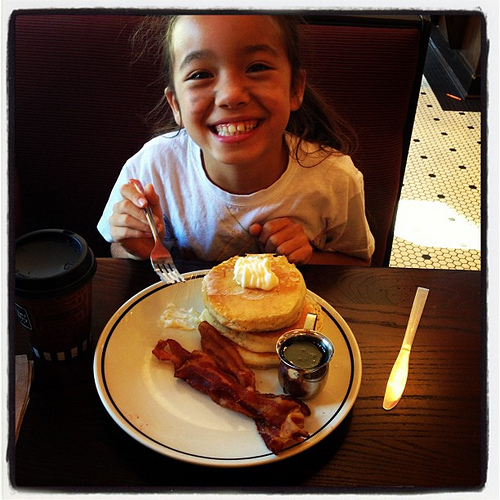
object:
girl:
[96, 9, 376, 267]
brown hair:
[132, 36, 361, 168]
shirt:
[96, 128, 376, 259]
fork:
[127, 178, 185, 285]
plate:
[92, 268, 362, 468]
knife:
[381, 286, 429, 411]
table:
[10, 257, 483, 489]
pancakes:
[200, 252, 324, 370]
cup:
[275, 312, 335, 401]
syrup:
[284, 340, 323, 368]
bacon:
[151, 319, 316, 454]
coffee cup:
[0, 228, 96, 367]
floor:
[387, 112, 483, 268]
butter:
[233, 256, 280, 291]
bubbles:
[303, 347, 306, 350]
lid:
[14, 227, 99, 295]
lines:
[333, 304, 479, 333]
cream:
[161, 271, 180, 283]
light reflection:
[394, 198, 481, 249]